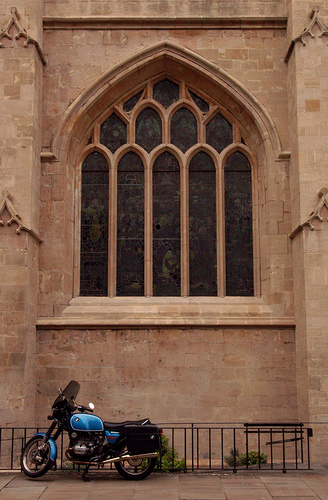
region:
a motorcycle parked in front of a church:
[7, 240, 205, 484]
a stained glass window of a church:
[75, 152, 110, 299]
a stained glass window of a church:
[116, 153, 143, 299]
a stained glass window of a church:
[152, 157, 179, 298]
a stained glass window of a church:
[186, 156, 220, 297]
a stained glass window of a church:
[225, 158, 252, 296]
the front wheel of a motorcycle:
[10, 429, 60, 481]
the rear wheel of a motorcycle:
[114, 439, 159, 479]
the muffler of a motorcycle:
[100, 447, 159, 466]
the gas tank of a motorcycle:
[65, 410, 106, 435]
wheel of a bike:
[18, 430, 57, 473]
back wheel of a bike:
[114, 434, 166, 471]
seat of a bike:
[99, 408, 149, 429]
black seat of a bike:
[105, 408, 155, 434]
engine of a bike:
[69, 434, 106, 460]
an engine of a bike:
[63, 436, 104, 462]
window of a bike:
[54, 378, 94, 401]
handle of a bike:
[77, 400, 101, 413]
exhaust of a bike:
[116, 443, 168, 465]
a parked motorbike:
[11, 377, 172, 487]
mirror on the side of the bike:
[88, 401, 95, 409]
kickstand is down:
[77, 465, 94, 483]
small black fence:
[0, 420, 319, 477]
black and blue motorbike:
[14, 371, 173, 483]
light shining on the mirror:
[86, 400, 96, 407]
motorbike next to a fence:
[0, 371, 311, 480]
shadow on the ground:
[28, 476, 54, 483]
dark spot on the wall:
[155, 354, 163, 365]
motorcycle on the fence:
[51, 417, 164, 476]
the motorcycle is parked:
[18, 436, 168, 489]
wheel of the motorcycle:
[115, 457, 152, 477]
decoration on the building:
[292, 191, 327, 253]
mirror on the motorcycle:
[71, 396, 93, 412]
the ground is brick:
[188, 485, 220, 496]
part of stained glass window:
[78, 154, 105, 295]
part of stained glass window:
[112, 161, 143, 296]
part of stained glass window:
[154, 157, 178, 294]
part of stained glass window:
[186, 153, 214, 294]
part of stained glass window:
[230, 153, 254, 294]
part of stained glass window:
[208, 122, 228, 148]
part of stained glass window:
[168, 113, 195, 146]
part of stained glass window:
[134, 110, 162, 143]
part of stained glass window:
[104, 125, 124, 143]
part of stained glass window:
[157, 83, 173, 101]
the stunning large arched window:
[66, 55, 259, 297]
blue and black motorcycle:
[19, 378, 163, 481]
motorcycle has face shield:
[48, 378, 80, 421]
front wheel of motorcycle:
[19, 430, 59, 480]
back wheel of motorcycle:
[111, 428, 157, 480]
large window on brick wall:
[76, 73, 255, 298]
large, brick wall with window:
[1, 73, 326, 466]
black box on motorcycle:
[124, 424, 162, 457]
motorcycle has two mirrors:
[56, 386, 95, 411]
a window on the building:
[225, 156, 254, 283]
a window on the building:
[191, 255, 226, 305]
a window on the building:
[143, 261, 174, 298]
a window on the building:
[82, 247, 96, 280]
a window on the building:
[175, 114, 194, 144]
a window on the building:
[137, 108, 154, 138]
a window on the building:
[105, 112, 126, 150]